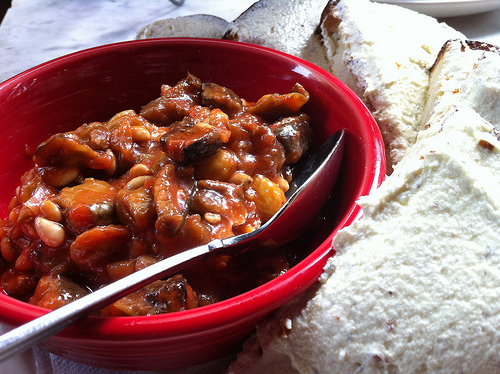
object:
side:
[33, 319, 247, 374]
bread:
[347, 17, 477, 94]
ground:
[470, 160, 481, 172]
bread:
[334, 225, 499, 373]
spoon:
[0, 128, 347, 363]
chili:
[0, 72, 316, 319]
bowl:
[0, 36, 387, 372]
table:
[0, 0, 500, 374]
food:
[0, 73, 311, 316]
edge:
[256, 167, 320, 236]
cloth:
[0, 0, 124, 47]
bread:
[398, 111, 494, 189]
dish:
[0, 37, 387, 374]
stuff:
[0, 0, 376, 374]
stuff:
[153, 0, 498, 320]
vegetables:
[0, 69, 316, 318]